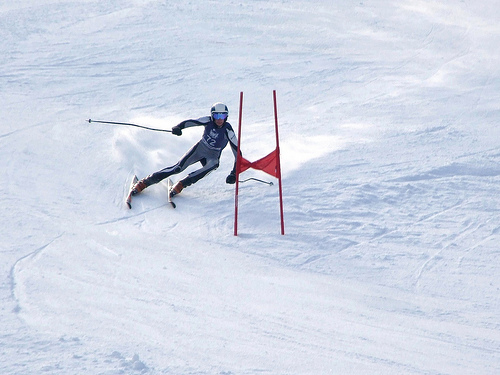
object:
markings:
[0, 192, 210, 375]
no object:
[84, 103, 276, 210]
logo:
[207, 129, 220, 140]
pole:
[231, 90, 242, 235]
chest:
[203, 127, 229, 147]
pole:
[232, 89, 246, 236]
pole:
[272, 88, 286, 236]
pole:
[85, 119, 177, 133]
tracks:
[285, 204, 500, 343]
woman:
[131, 103, 244, 198]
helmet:
[210, 103, 229, 119]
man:
[134, 103, 243, 203]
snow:
[0, 0, 500, 375]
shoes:
[128, 175, 185, 199]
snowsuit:
[132, 116, 246, 196]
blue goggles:
[211, 112, 229, 120]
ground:
[0, 229, 499, 375]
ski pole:
[85, 118, 176, 135]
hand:
[172, 125, 183, 136]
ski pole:
[235, 178, 275, 186]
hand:
[225, 172, 237, 184]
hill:
[0, 2, 498, 374]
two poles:
[231, 87, 285, 237]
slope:
[6, 0, 499, 375]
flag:
[238, 147, 279, 177]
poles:
[232, 88, 287, 236]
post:
[272, 89, 286, 236]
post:
[234, 90, 245, 233]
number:
[206, 134, 216, 146]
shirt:
[176, 116, 243, 170]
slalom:
[5, 1, 500, 366]